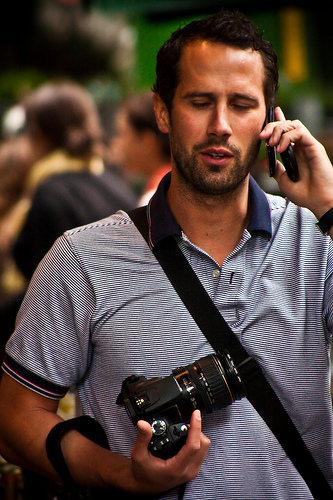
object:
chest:
[85, 302, 332, 442]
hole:
[228, 270, 236, 285]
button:
[212, 268, 220, 278]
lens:
[176, 351, 250, 414]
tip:
[215, 345, 248, 395]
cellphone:
[266, 104, 277, 179]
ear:
[264, 95, 276, 116]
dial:
[189, 355, 221, 413]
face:
[171, 42, 266, 195]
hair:
[150, 10, 279, 124]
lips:
[198, 144, 236, 166]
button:
[152, 416, 156, 421]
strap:
[126, 201, 333, 500]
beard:
[170, 135, 259, 206]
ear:
[153, 92, 171, 134]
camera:
[115, 347, 249, 460]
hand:
[120, 406, 211, 498]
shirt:
[4, 173, 333, 500]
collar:
[146, 169, 273, 251]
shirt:
[5, 168, 139, 257]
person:
[0, 79, 136, 290]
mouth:
[200, 146, 232, 166]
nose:
[206, 101, 232, 139]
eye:
[189, 99, 212, 108]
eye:
[230, 100, 255, 112]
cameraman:
[0, 13, 333, 494]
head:
[151, 12, 279, 205]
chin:
[198, 168, 237, 195]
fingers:
[173, 408, 212, 481]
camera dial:
[151, 418, 167, 436]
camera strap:
[44, 415, 111, 498]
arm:
[1, 247, 95, 497]